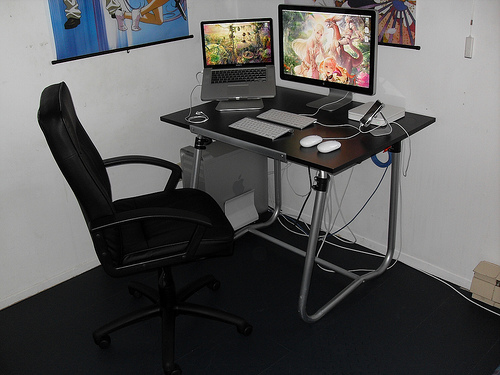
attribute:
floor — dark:
[0, 209, 500, 374]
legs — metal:
[190, 133, 400, 322]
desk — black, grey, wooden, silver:
[159, 81, 436, 323]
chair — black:
[37, 81, 253, 373]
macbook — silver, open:
[200, 17, 276, 103]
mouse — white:
[316, 139, 342, 154]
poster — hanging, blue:
[43, 0, 194, 66]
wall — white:
[237, 1, 500, 289]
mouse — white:
[300, 135, 325, 146]